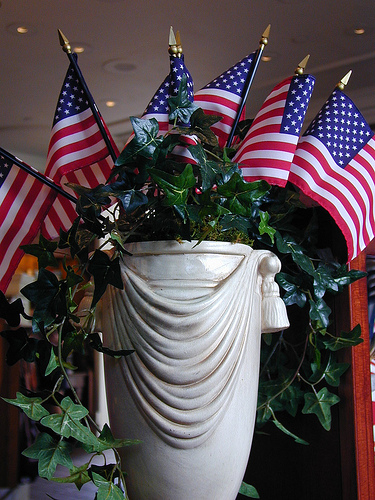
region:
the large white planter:
[73, 239, 290, 498]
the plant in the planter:
[0, 72, 369, 499]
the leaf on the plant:
[301, 386, 341, 432]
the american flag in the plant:
[286, 86, 374, 264]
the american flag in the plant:
[228, 72, 315, 185]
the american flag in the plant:
[192, 49, 245, 151]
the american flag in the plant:
[120, 54, 200, 174]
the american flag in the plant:
[43, 51, 121, 191]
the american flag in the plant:
[1, 147, 63, 301]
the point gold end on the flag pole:
[56, 26, 72, 54]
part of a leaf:
[304, 419, 317, 436]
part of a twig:
[85, 444, 96, 455]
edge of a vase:
[211, 429, 225, 440]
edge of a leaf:
[298, 372, 308, 385]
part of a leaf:
[69, 420, 82, 434]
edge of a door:
[345, 382, 351, 397]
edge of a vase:
[197, 362, 206, 374]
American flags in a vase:
[0, 1, 368, 498]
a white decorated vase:
[91, 236, 292, 498]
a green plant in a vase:
[26, 161, 344, 495]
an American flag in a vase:
[34, 23, 150, 278]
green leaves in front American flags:
[41, 41, 314, 236]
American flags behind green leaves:
[54, 23, 311, 255]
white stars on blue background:
[302, 84, 373, 166]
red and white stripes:
[235, 131, 298, 187]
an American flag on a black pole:
[32, 23, 119, 177]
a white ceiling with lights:
[0, 1, 371, 119]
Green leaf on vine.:
[55, 396, 100, 443]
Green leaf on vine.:
[305, 375, 337, 455]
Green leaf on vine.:
[160, 163, 202, 216]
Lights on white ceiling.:
[12, 20, 93, 61]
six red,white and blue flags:
[0, 51, 368, 260]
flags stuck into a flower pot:
[0, 63, 364, 259]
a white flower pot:
[84, 238, 281, 472]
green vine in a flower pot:
[31, 161, 281, 451]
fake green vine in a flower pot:
[29, 203, 326, 436]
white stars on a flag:
[64, 90, 79, 117]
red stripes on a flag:
[8, 180, 35, 245]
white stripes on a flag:
[14, 185, 40, 247]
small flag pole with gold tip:
[53, 22, 119, 175]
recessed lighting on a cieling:
[52, 33, 92, 60]